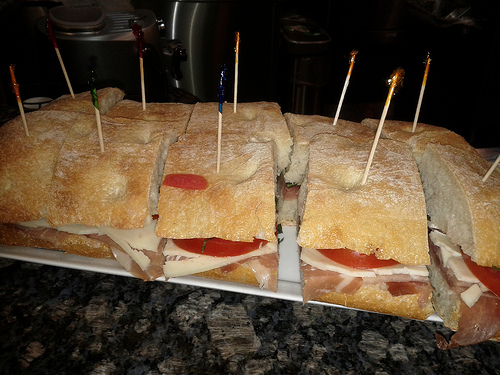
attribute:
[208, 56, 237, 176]
toothpick — blue, here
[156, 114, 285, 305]
sub sandwich — smaller, cut, here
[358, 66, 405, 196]
toothpick — orange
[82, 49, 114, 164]
toothpick — green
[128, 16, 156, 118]
toothpick — red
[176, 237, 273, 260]
tomato — red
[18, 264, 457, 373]
countertop — dark, marble, gray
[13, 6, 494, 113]
background — dark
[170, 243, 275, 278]
cheese — here, white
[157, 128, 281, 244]
bread — brown, italian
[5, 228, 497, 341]
serving plate — white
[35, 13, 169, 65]
meat slicer — steel